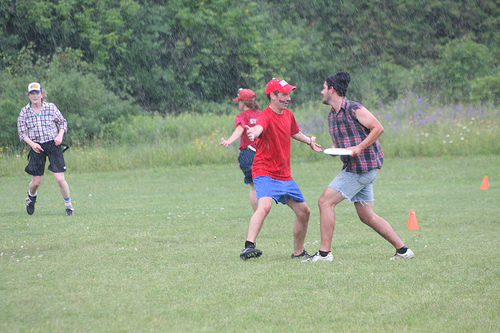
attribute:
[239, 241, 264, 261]
shoe — black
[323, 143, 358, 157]
frisbee — white, round, plastic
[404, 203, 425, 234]
cone — orange, small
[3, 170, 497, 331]
grass — green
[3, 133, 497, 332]
ground — large, green, grassy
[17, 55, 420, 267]
people — playing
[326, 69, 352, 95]
hat — knit cap, black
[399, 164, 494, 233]
cones — orange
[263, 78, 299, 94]
hat — red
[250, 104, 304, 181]
shirt — red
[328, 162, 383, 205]
shorts — jeans, jean cut offs, blue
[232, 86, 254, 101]
hat — red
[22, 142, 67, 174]
shorts — black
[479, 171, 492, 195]
cone — orange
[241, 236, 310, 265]
shoes — black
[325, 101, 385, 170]
shirt — sleeveless, plaid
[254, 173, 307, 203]
shorts — gray